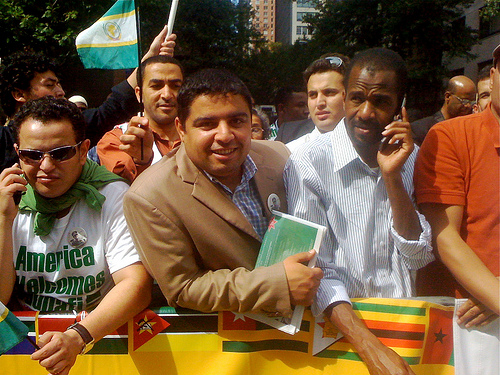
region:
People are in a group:
[0, 26, 496, 374]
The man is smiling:
[171, 65, 248, 171]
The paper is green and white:
[245, 210, 325, 333]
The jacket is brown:
[121, 140, 291, 315]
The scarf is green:
[5, 160, 120, 235]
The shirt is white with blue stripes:
[291, 118, 431, 319]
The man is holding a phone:
[377, 91, 405, 146]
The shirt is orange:
[413, 100, 498, 295]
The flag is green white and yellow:
[75, 0, 136, 67]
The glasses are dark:
[15, 146, 75, 161]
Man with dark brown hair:
[173, 68, 253, 183]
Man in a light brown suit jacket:
[121, 139, 320, 317]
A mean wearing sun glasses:
[11, 95, 93, 200]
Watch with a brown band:
[66, 318, 98, 358]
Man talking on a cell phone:
[341, 48, 416, 189]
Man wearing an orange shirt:
[415, 102, 497, 304]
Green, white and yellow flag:
[72, 0, 143, 80]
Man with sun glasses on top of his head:
[301, 50, 347, 137]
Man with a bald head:
[441, 75, 476, 117]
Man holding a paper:
[242, 204, 329, 334]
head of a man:
[173, 70, 283, 187]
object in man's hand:
[225, 205, 339, 340]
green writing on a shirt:
[8, 230, 113, 317]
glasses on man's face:
[16, 135, 88, 180]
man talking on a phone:
[344, 52, 424, 146]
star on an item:
[421, 311, 459, 357]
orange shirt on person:
[410, 108, 492, 209]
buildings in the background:
[245, 0, 315, 40]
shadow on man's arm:
[407, 138, 463, 242]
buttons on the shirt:
[364, 190, 393, 297]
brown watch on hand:
[63, 317, 96, 352]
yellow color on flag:
[152, 345, 276, 374]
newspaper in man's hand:
[242, 212, 339, 338]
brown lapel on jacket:
[181, 176, 263, 238]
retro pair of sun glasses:
[6, 138, 104, 166]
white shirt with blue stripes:
[283, 137, 435, 309]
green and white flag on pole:
[69, 5, 166, 145]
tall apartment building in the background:
[245, 7, 295, 50]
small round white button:
[261, 190, 289, 213]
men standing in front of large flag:
[31, 47, 488, 318]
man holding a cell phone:
[291, 38, 436, 373]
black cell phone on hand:
[376, 90, 414, 172]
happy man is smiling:
[118, 73, 329, 337]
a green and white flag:
[61, 3, 187, 75]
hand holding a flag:
[69, 0, 191, 67]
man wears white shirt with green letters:
[1, 90, 154, 373]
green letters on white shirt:
[6, 186, 138, 323]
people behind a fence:
[0, 45, 499, 373]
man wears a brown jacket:
[113, 67, 321, 348]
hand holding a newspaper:
[238, 204, 332, 348]